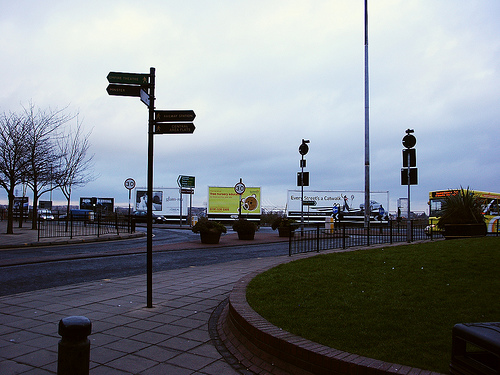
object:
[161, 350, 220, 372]
brick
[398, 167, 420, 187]
signal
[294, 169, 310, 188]
signal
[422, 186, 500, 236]
bus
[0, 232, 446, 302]
road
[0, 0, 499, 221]
clouds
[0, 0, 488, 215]
sky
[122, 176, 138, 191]
sign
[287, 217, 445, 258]
metal fence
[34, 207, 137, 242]
metal fence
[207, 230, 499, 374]
park square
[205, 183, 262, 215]
billboard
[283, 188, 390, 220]
billboard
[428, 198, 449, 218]
front windshield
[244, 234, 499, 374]
grass green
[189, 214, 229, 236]
flowers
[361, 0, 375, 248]
post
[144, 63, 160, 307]
pole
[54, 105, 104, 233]
tree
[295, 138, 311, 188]
three signs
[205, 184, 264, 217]
advertisement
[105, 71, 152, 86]
sign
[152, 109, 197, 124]
sign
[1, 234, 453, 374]
walkway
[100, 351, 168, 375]
stone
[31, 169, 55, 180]
leaves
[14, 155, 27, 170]
leaves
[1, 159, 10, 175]
leaves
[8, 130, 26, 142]
leaves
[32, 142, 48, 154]
leaves